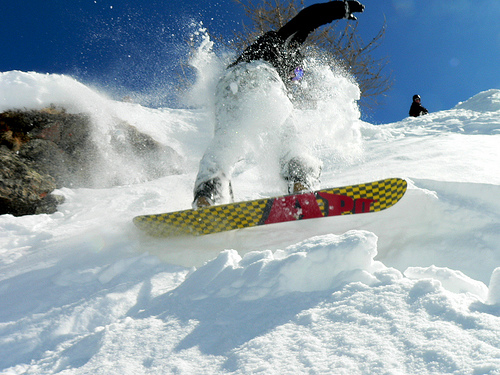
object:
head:
[412, 94, 421, 103]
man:
[409, 94, 430, 117]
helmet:
[413, 94, 421, 101]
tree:
[178, 0, 399, 115]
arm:
[275, 0, 365, 51]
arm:
[417, 105, 429, 114]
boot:
[279, 156, 321, 196]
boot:
[190, 175, 234, 209]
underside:
[168, 188, 402, 225]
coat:
[226, 0, 344, 90]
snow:
[0, 57, 496, 372]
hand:
[337, 0, 365, 21]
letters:
[258, 191, 378, 225]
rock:
[0, 107, 188, 219]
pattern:
[157, 214, 229, 229]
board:
[132, 177, 407, 243]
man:
[191, 0, 365, 210]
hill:
[0, 68, 500, 375]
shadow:
[126, 251, 336, 358]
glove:
[344, 0, 365, 21]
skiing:
[133, 0, 408, 241]